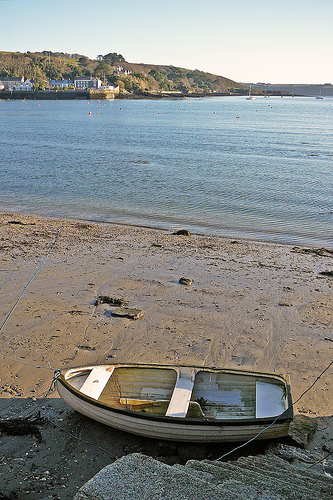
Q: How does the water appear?
A: Calm.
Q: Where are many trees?
A: In the distance.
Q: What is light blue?
A: Sky.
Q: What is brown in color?
A: Sand.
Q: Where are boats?
A: In the water.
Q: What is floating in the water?
A: Boats.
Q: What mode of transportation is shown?
A: Boat.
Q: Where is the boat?
A: Shore.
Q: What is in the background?
A: Hills.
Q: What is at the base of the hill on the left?
A: Buildings.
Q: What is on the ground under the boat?
A: Sand.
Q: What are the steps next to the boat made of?
A: Concrete.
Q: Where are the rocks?
A: In the sand.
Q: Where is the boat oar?
A: In the boat.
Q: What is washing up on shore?
A: Waves.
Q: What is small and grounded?
A: The wooden boat.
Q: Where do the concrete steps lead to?
A: The beach.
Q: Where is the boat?
A: In the sand.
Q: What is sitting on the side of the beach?
A: A boat.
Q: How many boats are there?
A: One.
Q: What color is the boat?
A: White.